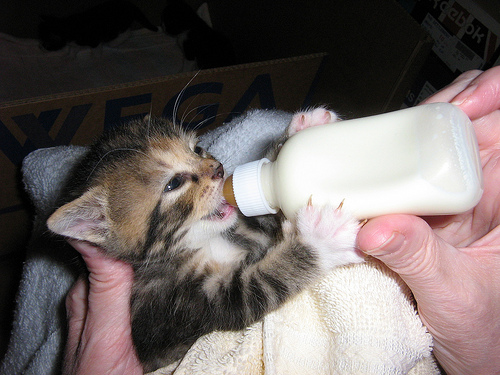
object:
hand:
[62, 235, 145, 373]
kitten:
[42, 72, 371, 374]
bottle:
[221, 101, 487, 227]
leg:
[205, 242, 330, 335]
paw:
[280, 194, 371, 267]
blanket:
[169, 256, 442, 374]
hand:
[351, 63, 499, 373]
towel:
[0, 110, 293, 372]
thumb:
[352, 212, 486, 327]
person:
[53, 62, 500, 374]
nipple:
[221, 171, 238, 211]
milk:
[260, 101, 486, 223]